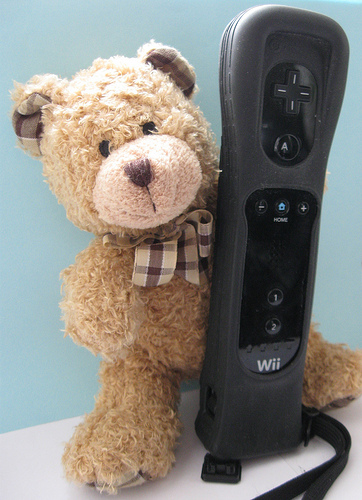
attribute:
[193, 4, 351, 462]
wii — black, gray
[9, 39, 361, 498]
bear — brown, standing, beige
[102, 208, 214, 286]
scarf — brown, yellow, plaid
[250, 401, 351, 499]
strap — black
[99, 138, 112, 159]
eye — button, dark, black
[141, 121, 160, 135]
eye — button, dark, black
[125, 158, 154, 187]
nose — brown, black, dark brown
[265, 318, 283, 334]
button — round, blue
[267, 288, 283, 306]
button — round, blue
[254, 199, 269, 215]
button — blue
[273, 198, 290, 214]
button — blue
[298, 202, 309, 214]
button — blue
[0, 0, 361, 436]
background — blue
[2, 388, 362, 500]
object — white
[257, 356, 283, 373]
lettering — white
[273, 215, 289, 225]
lettering — white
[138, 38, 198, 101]
ear — plaid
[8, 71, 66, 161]
ear — plaid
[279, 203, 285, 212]
icon — blue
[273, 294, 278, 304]
number — one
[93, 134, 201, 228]
snout — pink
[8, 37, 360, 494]
fur — brown